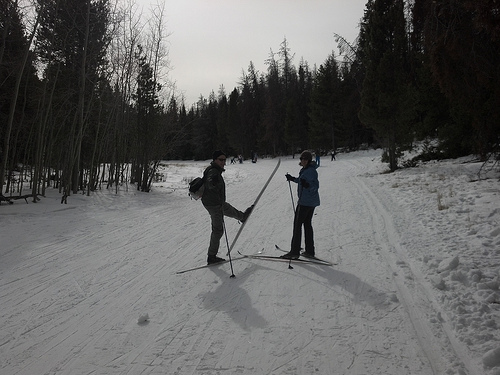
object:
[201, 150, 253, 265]
person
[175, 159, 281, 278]
equipment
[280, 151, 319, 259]
person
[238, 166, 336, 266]
equipment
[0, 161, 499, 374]
snow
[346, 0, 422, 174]
tree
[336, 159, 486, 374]
trail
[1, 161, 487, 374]
path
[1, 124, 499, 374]
hill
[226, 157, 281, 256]
ski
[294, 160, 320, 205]
jacket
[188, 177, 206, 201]
backpack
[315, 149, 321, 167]
person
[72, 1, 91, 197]
tree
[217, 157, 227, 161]
sunglasses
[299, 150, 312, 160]
hat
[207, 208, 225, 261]
leg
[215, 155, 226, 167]
face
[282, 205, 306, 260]
leg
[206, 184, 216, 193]
elbow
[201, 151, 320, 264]
couple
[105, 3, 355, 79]
sky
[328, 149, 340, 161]
people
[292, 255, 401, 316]
shadows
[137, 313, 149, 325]
ice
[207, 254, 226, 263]
feet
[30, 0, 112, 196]
trees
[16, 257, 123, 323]
marks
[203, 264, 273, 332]
shadow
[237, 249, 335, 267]
skis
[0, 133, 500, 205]
bottom